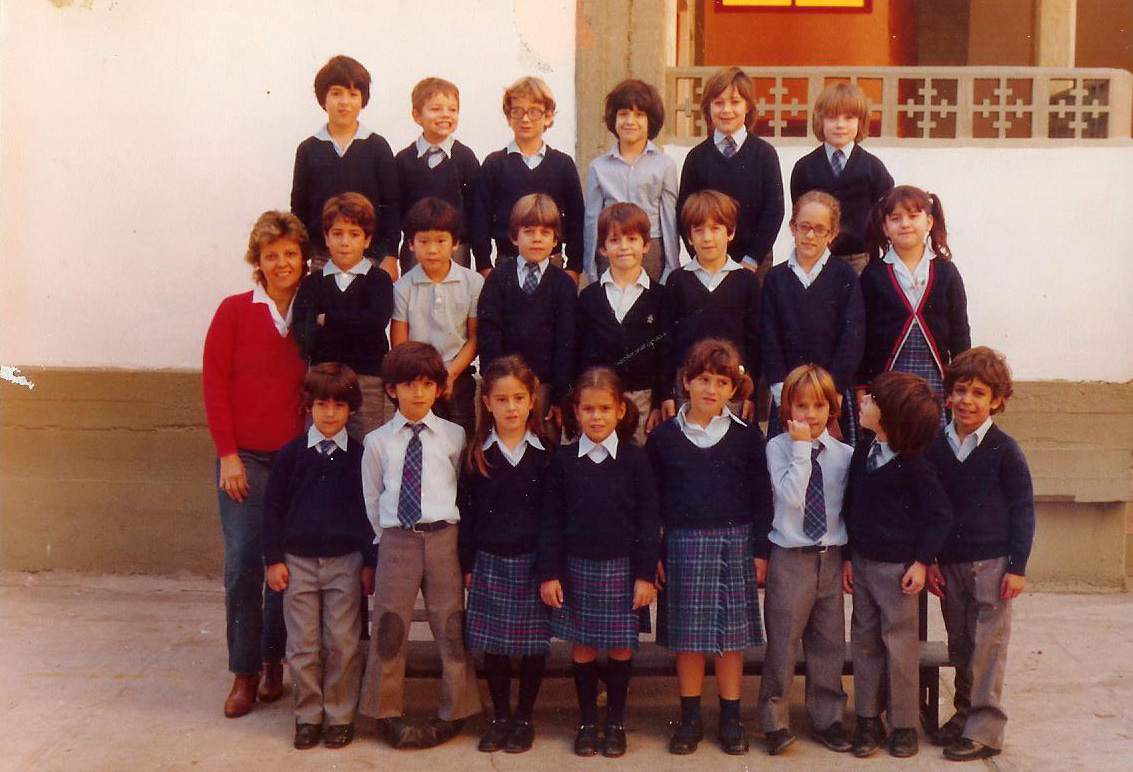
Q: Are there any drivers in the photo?
A: No, there are no drivers.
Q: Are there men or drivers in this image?
A: No, there are no drivers or men.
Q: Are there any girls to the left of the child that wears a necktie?
A: Yes, there is a girl to the left of the kid.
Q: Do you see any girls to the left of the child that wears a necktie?
A: Yes, there is a girl to the left of the kid.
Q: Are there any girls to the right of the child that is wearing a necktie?
A: No, the girl is to the left of the kid.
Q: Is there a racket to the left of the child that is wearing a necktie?
A: No, there is a girl to the left of the kid.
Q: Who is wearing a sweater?
A: The girl is wearing a sweater.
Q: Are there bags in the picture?
A: No, there are no bags.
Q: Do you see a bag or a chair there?
A: No, there are no bags or chairs.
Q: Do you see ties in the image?
A: Yes, there is a tie.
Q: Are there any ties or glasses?
A: Yes, there is a tie.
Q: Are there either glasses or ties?
A: Yes, there is a tie.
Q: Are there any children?
A: Yes, there is a child.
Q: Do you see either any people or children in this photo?
A: Yes, there is a child.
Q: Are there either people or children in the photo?
A: Yes, there is a child.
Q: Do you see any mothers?
A: No, there are no mothers.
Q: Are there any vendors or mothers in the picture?
A: No, there are no mothers or vendors.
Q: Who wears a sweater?
A: The child wears a sweater.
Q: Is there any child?
A: Yes, there is a child.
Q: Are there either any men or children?
A: Yes, there is a child.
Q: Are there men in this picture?
A: No, there are no men.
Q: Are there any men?
A: No, there are no men.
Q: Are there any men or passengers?
A: No, there are no men or passengers.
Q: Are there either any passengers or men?
A: No, there are no men or passengers.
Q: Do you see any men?
A: No, there are no men.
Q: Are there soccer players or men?
A: No, there are no men or soccer players.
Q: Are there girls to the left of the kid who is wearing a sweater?
A: Yes, there is a girl to the left of the kid.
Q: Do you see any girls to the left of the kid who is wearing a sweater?
A: Yes, there is a girl to the left of the kid.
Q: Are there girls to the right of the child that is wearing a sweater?
A: No, the girl is to the left of the kid.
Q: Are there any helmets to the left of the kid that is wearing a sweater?
A: No, there is a girl to the left of the child.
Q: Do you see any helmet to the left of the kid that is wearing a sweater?
A: No, there is a girl to the left of the child.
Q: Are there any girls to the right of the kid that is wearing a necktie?
A: No, the girl is to the left of the child.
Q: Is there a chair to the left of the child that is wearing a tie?
A: No, there is a girl to the left of the child.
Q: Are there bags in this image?
A: No, there are no bags.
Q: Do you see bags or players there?
A: No, there are no bags or players.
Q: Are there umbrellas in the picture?
A: No, there are no umbrellas.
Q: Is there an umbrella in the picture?
A: No, there are no umbrellas.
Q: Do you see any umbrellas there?
A: No, there are no umbrellas.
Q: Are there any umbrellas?
A: No, there are no umbrellas.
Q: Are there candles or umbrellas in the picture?
A: No, there are no umbrellas or candles.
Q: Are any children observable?
A: Yes, there is a child.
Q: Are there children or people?
A: Yes, there is a child.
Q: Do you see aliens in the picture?
A: No, there are no aliens.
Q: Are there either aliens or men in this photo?
A: No, there are no aliens or men.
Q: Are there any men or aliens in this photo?
A: No, there are no aliens or men.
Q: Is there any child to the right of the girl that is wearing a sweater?
A: Yes, there is a child to the right of the girl.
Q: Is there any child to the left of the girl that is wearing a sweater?
A: No, the child is to the right of the girl.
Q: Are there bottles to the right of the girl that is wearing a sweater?
A: No, there is a child to the right of the girl.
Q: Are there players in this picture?
A: No, there are no players.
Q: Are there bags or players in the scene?
A: No, there are no players or bags.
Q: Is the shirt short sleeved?
A: Yes, the shirt is short sleeved.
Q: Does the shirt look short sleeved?
A: Yes, the shirt is short sleeved.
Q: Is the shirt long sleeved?
A: No, the shirt is short sleeved.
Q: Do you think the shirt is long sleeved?
A: No, the shirt is short sleeved.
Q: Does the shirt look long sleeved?
A: No, the shirt is short sleeved.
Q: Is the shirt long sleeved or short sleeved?
A: The shirt is short sleeved.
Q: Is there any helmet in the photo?
A: No, there are no helmets.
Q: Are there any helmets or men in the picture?
A: No, there are no helmets or men.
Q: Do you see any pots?
A: No, there are no pots.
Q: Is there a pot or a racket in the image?
A: No, there are no pots or rackets.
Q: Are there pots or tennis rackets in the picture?
A: No, there are no pots or tennis rackets.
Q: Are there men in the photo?
A: No, there are no men.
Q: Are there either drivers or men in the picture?
A: No, there are no men or drivers.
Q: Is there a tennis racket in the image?
A: No, there are no rackets.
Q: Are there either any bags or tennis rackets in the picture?
A: No, there are no tennis rackets or bags.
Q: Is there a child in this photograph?
A: Yes, there is a child.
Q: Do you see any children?
A: Yes, there is a child.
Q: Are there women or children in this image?
A: Yes, there is a child.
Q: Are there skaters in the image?
A: No, there are no skaters.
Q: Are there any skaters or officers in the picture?
A: No, there are no skaters or officers.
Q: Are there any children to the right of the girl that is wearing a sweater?
A: Yes, there is a child to the right of the girl.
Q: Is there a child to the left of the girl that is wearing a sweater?
A: No, the child is to the right of the girl.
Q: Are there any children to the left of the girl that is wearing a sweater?
A: No, the child is to the right of the girl.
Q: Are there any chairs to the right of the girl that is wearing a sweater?
A: No, there is a child to the right of the girl.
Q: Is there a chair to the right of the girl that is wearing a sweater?
A: No, there is a child to the right of the girl.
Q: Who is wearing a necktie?
A: The kid is wearing a necktie.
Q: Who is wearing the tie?
A: The kid is wearing a necktie.